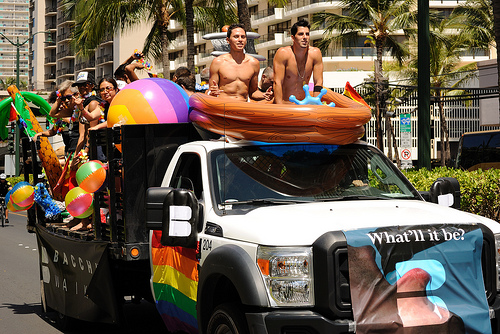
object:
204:
[201, 238, 214, 251]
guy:
[274, 18, 327, 107]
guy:
[207, 21, 274, 97]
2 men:
[208, 19, 321, 103]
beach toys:
[34, 182, 69, 223]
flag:
[147, 224, 200, 331]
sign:
[400, 116, 412, 146]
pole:
[412, 2, 434, 171]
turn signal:
[256, 256, 271, 277]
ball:
[104, 73, 193, 126]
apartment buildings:
[151, 1, 499, 156]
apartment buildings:
[1, 0, 153, 172]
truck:
[23, 128, 488, 328]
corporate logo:
[341, 224, 495, 332]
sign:
[212, 237, 215, 251]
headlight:
[267, 247, 316, 278]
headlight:
[257, 274, 312, 309]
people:
[51, 79, 89, 132]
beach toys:
[3, 84, 75, 200]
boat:
[187, 84, 368, 144]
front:
[313, 226, 500, 329]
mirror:
[161, 204, 191, 240]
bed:
[26, 198, 146, 274]